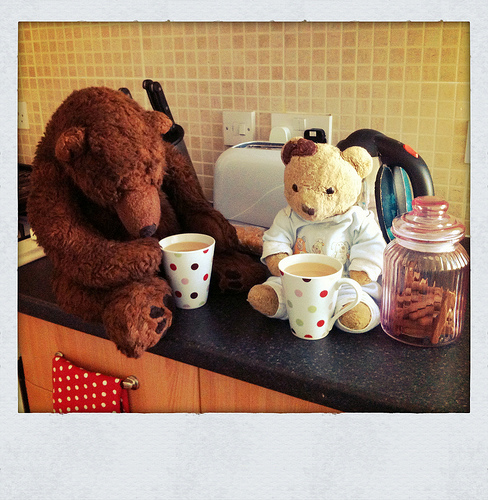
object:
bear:
[19, 75, 274, 364]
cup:
[146, 208, 232, 315]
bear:
[241, 118, 396, 345]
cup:
[261, 240, 374, 360]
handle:
[328, 273, 368, 332]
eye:
[285, 179, 307, 195]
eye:
[321, 182, 344, 198]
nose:
[112, 184, 166, 246]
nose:
[289, 197, 323, 220]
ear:
[49, 123, 94, 166]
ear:
[136, 100, 175, 141]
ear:
[338, 132, 380, 177]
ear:
[271, 127, 322, 165]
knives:
[150, 73, 205, 204]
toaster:
[199, 126, 371, 246]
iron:
[332, 124, 446, 267]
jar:
[371, 183, 475, 356]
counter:
[19, 206, 472, 411]